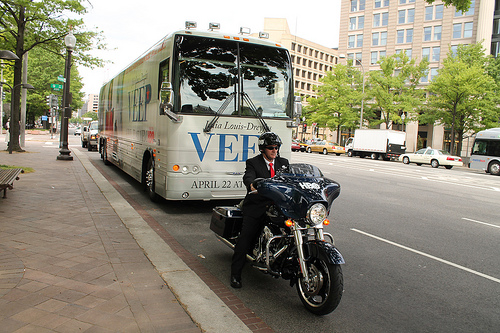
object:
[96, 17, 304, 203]
bus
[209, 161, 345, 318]
motorcycle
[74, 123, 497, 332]
street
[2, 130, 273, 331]
sidewalk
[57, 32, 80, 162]
lamp post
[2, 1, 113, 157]
tree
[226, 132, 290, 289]
man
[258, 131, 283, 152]
helmet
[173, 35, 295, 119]
windshield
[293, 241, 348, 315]
tire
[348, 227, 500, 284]
line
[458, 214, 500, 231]
line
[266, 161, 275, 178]
tie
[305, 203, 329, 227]
headlight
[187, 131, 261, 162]
letters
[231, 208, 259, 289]
leg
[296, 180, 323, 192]
logo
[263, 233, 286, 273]
engine guard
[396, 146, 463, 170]
cab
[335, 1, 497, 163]
building